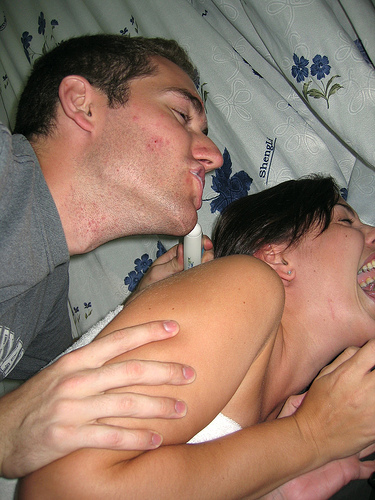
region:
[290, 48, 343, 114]
blue flowers on green stems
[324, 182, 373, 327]
laughing face of a young woman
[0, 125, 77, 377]
grey t-shirt with white print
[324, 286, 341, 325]
scratch on girls face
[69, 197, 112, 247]
razor burn on throat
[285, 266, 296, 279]
stud earring on the woman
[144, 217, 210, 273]
hand holds an electric toothbrush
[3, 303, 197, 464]
a man's right hand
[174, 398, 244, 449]
a woman's white top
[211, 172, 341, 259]
dark hair of a woman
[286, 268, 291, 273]
earring of a woman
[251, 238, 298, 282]
woman's right ear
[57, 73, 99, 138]
right ear of a man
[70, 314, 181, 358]
man's index finger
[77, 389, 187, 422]
man's right ring finger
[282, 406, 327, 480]
right wrist of a woman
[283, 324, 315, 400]
neck of a woman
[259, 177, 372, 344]
the woman is laughing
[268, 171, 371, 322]
the woman is laughing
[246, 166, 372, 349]
the woman is laughing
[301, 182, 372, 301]
the woman is laughing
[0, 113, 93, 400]
the shirt is gray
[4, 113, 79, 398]
the shirt is gray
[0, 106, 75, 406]
the shirt is gray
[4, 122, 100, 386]
the shirt is gray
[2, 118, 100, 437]
the shirt is gray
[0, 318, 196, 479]
The hand of a man with very pink fingernails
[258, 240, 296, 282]
Woman's ear with a stud type pierced earring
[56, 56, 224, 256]
Man's face with dark razor stubble on his face and neck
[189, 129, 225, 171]
Man's nose that is pointed and beak shaped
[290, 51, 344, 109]
Two bluish purple flowers which are patterned on bedding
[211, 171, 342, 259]
Dark hair of a woman lying on a bed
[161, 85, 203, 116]
Unruly black hair eyebrow of a man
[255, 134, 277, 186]
The word Shengli in blue patterned on a bedsheet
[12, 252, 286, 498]
Arm of woman with a few freckles on the upper portion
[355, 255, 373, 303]
Woman's laughing mouth wide open with yellow teeth showing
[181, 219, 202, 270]
electric toothbrush in man's mouth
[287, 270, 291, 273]
earring in woman's ear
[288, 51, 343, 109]
blue flowers print on sheet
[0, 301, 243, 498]
white towel wrapped around woman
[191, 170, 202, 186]
toothpaste foam on man's mouth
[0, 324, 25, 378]
logo on front of man's shirt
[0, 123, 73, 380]
gray shirt on man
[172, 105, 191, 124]
eye on man's face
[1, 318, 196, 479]
man's hand on woman's arm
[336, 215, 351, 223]
eye on woman's face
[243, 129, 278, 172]
black words on sheet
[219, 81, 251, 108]
white design on sheet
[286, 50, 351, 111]
blue and gray design